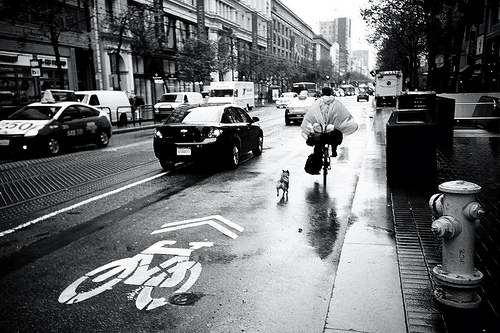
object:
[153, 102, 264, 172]
car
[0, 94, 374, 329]
street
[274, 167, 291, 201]
dog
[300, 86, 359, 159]
person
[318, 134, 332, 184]
bicycle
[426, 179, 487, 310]
fire hydrant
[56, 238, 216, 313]
bicycle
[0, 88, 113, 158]
taxi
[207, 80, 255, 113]
truck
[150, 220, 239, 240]
arrows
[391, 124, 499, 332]
sidewalk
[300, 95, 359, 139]
raincoat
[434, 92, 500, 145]
subway entrance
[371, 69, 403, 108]
truck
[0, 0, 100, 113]
buildings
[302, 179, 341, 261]
reflection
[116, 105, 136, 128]
fences